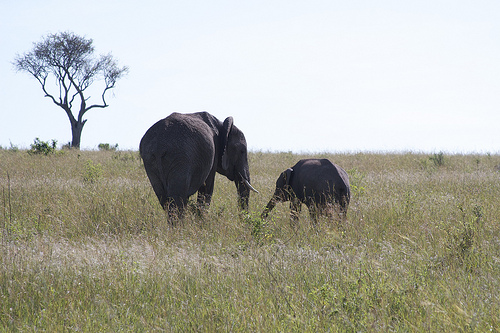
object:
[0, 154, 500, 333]
field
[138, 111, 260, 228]
elephant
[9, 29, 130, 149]
tree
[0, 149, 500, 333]
grass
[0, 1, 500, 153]
sky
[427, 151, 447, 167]
bush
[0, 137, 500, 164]
horizon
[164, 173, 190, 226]
leg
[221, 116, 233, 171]
ear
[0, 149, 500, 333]
plain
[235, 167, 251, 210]
trunk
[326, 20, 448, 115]
sun